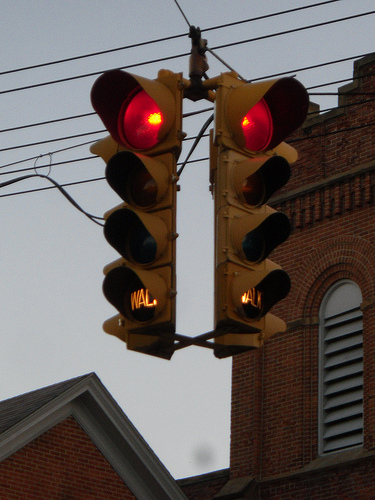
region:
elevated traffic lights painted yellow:
[26, 12, 326, 372]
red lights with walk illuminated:
[78, 68, 295, 357]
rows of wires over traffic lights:
[26, 0, 341, 176]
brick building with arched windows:
[222, 68, 363, 479]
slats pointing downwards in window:
[295, 273, 361, 455]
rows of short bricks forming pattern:
[259, 158, 367, 223]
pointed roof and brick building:
[15, 341, 150, 476]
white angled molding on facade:
[4, 366, 190, 488]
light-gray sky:
[15, 219, 83, 355]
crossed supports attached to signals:
[160, 57, 229, 365]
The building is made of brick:
[232, 177, 367, 479]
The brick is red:
[231, 360, 314, 473]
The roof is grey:
[9, 376, 125, 451]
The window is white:
[304, 271, 373, 445]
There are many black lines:
[11, 3, 345, 201]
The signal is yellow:
[88, 47, 304, 362]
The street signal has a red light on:
[96, 74, 304, 169]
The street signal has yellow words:
[112, 250, 290, 353]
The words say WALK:
[100, 268, 274, 335]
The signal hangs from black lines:
[134, 1, 274, 114]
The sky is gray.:
[24, 11, 99, 37]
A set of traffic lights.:
[54, 48, 343, 370]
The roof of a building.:
[0, 367, 112, 438]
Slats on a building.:
[319, 315, 364, 423]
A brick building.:
[249, 360, 309, 450]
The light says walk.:
[225, 263, 295, 350]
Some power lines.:
[0, 19, 193, 85]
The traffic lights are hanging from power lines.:
[77, 1, 332, 361]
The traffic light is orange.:
[65, 63, 185, 148]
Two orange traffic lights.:
[68, 52, 314, 153]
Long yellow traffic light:
[216, 74, 304, 349]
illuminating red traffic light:
[235, 84, 279, 156]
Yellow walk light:
[239, 283, 269, 318]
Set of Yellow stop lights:
[102, 65, 296, 367]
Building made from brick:
[36, 452, 94, 496]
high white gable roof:
[48, 371, 121, 436]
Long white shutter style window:
[316, 287, 367, 452]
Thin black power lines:
[1, 131, 86, 195]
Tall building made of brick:
[284, 51, 374, 495]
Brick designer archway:
[297, 241, 374, 284]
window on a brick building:
[302, 267, 374, 463]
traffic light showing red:
[195, 64, 319, 360]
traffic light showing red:
[84, 67, 189, 355]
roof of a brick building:
[0, 365, 201, 498]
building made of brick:
[190, 55, 374, 498]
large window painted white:
[309, 276, 370, 458]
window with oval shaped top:
[306, 277, 370, 459]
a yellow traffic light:
[82, 61, 195, 362]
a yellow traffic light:
[194, 67, 323, 362]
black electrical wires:
[0, 171, 103, 242]